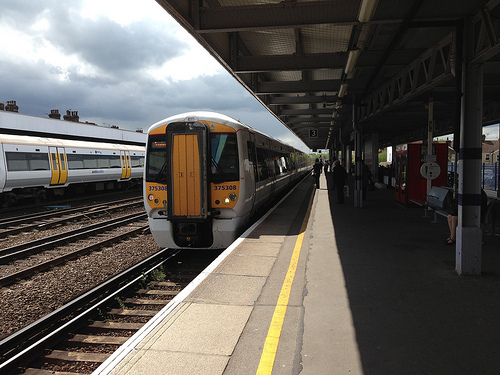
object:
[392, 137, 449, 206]
vending machine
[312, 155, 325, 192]
people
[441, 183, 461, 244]
woman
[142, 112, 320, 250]
train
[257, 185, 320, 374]
line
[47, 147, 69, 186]
doors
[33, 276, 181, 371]
planks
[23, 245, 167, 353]
rods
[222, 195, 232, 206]
light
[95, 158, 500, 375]
platform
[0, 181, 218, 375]
tracks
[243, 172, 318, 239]
shadow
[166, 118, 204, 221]
doors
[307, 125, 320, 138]
sign